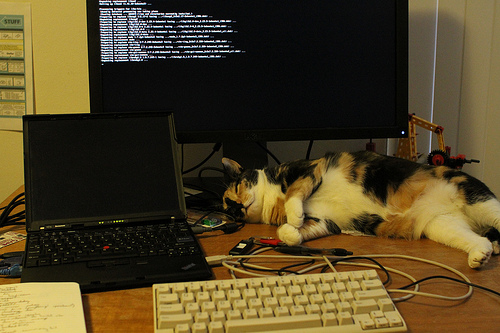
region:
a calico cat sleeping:
[203, 149, 488, 264]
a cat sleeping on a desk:
[210, 121, 487, 254]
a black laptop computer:
[16, 114, 208, 285]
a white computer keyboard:
[129, 250, 407, 332]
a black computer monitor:
[73, 18, 430, 153]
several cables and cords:
[212, 248, 468, 291]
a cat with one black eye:
[216, 149, 258, 226]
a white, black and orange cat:
[208, 154, 487, 251]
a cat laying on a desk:
[205, 139, 488, 251]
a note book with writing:
[2, 273, 92, 332]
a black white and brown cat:
[210, 148, 499, 266]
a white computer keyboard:
[148, 267, 408, 331]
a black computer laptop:
[20, 112, 212, 292]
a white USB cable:
[204, 250, 470, 305]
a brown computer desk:
[6, 181, 496, 331]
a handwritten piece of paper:
[0, 278, 90, 331]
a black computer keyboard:
[29, 225, 201, 264]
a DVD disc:
[0, 249, 25, 279]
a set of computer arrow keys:
[356, 308, 401, 327]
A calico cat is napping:
[198, 135, 498, 277]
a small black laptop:
[17, 101, 225, 301]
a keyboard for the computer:
[141, 270, 418, 331]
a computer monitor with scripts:
[73, 1, 420, 156]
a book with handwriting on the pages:
[1, 276, 104, 331]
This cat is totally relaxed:
[208, 158, 325, 246]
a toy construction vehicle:
[390, 103, 485, 175]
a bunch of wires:
[211, 228, 491, 329]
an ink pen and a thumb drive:
[231, 233, 354, 260]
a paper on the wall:
[1, 4, 43, 130]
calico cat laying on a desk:
[214, 155, 499, 273]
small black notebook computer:
[22, 112, 214, 287]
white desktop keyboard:
[150, 271, 405, 331]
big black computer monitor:
[87, 0, 407, 161]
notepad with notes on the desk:
[2, 280, 86, 332]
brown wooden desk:
[0, 180, 497, 332]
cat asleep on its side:
[224, 156, 499, 268]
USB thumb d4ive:
[229, 237, 257, 255]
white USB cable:
[207, 253, 471, 304]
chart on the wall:
[2, 13, 32, 129]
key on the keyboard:
[191, 313, 205, 320]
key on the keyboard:
[210, 310, 230, 322]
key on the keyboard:
[224, 303, 236, 317]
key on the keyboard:
[203, 300, 217, 310]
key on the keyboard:
[323, 313, 340, 323]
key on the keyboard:
[338, 310, 350, 322]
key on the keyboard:
[195, 321, 204, 330]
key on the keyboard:
[376, 297, 393, 309]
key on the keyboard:
[358, 314, 373, 327]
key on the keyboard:
[378, 316, 385, 326]